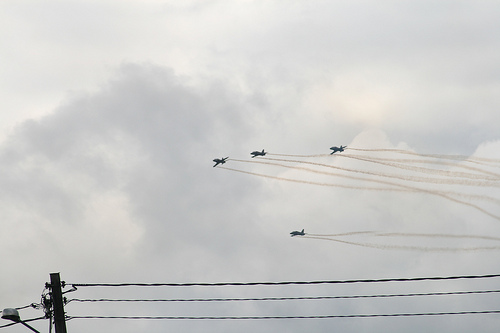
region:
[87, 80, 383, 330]
planes flying in the air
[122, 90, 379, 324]
planes near electrical line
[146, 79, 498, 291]
planes with smoke in air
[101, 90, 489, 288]
smoke being released in the air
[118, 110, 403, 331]
smoke being released from planes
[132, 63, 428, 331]
planes releasing smoke into the air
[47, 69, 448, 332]
planes releasing smoke into the atmospehre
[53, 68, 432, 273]
planes in the sky rolling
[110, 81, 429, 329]
planes doing stuns in the air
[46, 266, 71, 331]
Electrical power pole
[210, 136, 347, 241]
Airplane flying in the sky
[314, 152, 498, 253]
Contrails in the sky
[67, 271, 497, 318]
Overhead power lines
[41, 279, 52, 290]
Pea knob on side of power pole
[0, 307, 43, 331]
Mounted overhead light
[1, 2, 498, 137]
Grey sky with white fluffy clouds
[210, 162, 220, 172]
Left wing on flying airplane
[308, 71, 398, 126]
Bright white cloud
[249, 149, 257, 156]
Cockpit on flying airplane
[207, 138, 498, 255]
four jets in the sky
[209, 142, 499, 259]
jets leaving behind smoke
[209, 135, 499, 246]
planes flying together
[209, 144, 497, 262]
jets facing left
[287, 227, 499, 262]
jet leaves a trail behind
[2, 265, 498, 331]
black power lines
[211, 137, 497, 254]
jets flying away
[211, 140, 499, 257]
jets flying on a cloudy day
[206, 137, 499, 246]
jets travelling together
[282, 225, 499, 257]
plane flying away in the sky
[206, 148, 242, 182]
this is a plane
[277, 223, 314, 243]
this is a plane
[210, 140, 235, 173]
this is a plane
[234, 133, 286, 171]
this is a plane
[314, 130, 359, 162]
this is a plane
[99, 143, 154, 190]
this is a cloud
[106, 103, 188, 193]
this is a cloud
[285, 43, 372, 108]
this is a cloud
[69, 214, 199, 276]
this is a cloud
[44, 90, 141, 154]
this is a cloud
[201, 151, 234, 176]
The leading plane flying.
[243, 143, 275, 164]
The second plane in formation.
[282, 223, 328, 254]
The plane lowest to the ground.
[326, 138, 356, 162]
The fourth plane in formation.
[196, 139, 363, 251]
A group of jets flying in formation.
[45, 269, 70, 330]
A telephone pole colored black.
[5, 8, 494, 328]
It is a very cloudy day.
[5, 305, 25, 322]
The bulb of a street lamp.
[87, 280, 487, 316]
Telephone lines running in parallel.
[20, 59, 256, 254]
A very grey looking cloud.